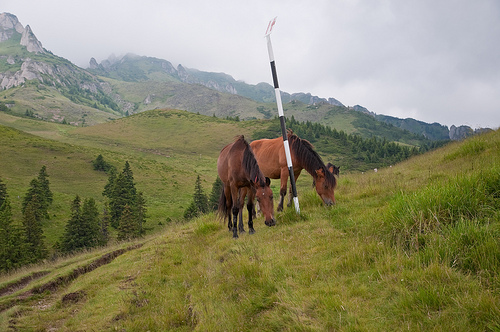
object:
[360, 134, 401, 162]
trees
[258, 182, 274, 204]
spot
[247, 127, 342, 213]
horse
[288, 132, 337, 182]
mane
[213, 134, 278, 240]
horse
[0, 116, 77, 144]
grass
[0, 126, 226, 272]
hill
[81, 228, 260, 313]
grass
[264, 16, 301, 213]
pole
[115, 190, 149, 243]
pine tree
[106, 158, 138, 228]
pine tree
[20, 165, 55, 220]
pine tree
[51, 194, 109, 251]
pine tree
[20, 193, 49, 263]
pine tree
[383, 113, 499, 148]
mountains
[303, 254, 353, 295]
grass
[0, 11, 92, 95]
rocky mountain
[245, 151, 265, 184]
mane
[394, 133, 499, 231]
grass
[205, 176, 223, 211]
tree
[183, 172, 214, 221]
tree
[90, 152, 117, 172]
tree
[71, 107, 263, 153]
green hill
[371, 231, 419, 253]
part